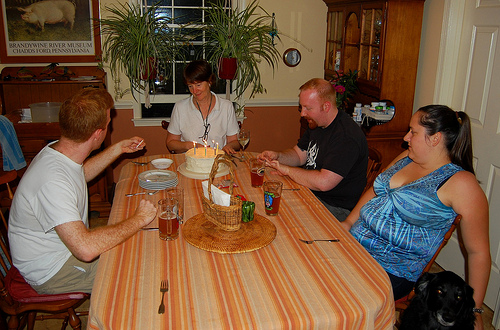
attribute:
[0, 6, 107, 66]
picture — pig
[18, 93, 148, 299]
man — haired, red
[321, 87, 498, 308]
woman — brunette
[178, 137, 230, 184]
cake — birthday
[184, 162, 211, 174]
icing — white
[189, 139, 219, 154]
candles — lite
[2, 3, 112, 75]
poster — framed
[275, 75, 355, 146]
main — haired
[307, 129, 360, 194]
shirt — black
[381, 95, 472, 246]
lady — blue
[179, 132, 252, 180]
candles — lit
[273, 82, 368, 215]
man — redhead, bearded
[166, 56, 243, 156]
woman — middle-aged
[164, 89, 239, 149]
shirt — polo, white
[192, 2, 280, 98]
plant — green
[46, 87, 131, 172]
man — redhead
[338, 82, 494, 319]
lady — brunette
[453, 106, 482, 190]
ponytail — high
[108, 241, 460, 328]
tablecloth — striped, orange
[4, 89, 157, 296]
guy — red, head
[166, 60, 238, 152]
woman — middle-aged, caucasian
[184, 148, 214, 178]
cake — white, birthday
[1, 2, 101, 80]
frame — wood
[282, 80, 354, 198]
man — red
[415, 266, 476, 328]
dog — black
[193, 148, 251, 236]
holder — napkin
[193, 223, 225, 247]
placemat — wicker, brown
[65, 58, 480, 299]
party — birthday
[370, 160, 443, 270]
top — sleeveless, blue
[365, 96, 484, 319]
woman — brunette, overweight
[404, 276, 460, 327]
dog — black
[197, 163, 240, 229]
basket — wicker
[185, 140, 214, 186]
cake — birthday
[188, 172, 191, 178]
plate — white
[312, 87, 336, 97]
hair — short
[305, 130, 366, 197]
shirt — short, sleeve, black, tee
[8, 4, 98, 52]
poster — museum, brandywine river 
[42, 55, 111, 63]
frame — wooden